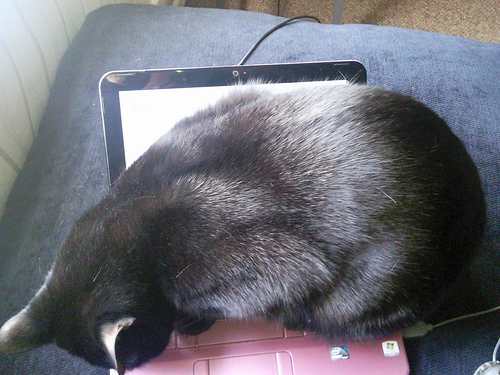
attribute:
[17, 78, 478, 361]
cat — standing, black  , under 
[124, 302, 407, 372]
board — pink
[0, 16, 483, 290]
blanket — blue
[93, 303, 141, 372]
ear — shining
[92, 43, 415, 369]
lap top — Small , pretty , pink 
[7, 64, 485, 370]
cat — Black 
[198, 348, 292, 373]
mouse — Pink , touch screen 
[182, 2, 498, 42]
carpet — Short , brown , shag 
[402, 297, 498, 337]
computer cord — White 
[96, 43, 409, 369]
laptop — pink 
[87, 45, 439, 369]
laptop computer — pink , windows 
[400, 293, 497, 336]
cord — green 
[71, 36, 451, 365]
laptop — open 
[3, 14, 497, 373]
pillow — large, blue 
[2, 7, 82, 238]
pillow — white , green 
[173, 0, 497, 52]
carpet — brown 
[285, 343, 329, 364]
laptop — pink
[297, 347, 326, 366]
laptop — pink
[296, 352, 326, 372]
laptop — pink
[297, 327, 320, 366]
laptop — pink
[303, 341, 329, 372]
laptop — pink